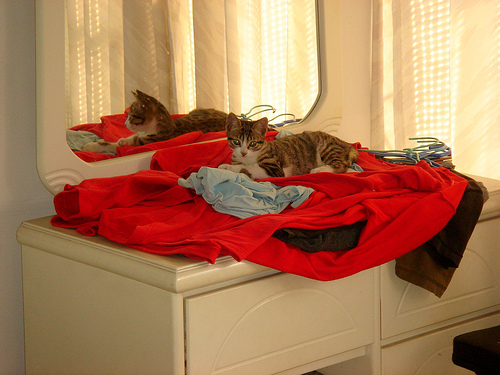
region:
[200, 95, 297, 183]
the head of a cat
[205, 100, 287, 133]
the ears of a cat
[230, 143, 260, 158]
the nose of a cat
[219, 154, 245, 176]
the paw of a cat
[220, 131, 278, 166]
the eyes of a cat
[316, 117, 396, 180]
the tail of a cat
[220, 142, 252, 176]
the mouth of a cat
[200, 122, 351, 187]
the body of a cat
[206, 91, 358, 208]
a cat laying down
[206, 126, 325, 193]
the leg of a cat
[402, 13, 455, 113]
curtains over the window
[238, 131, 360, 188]
cat on the blanket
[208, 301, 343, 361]
drawer of the cabinet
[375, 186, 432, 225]
the blanket is red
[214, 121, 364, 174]
the cat is laying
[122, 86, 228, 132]
reflection of the cat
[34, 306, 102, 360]
side of the cabinet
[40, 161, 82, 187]
corner of the mirror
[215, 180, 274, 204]
the clothing is blue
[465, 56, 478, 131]
the curtains are tan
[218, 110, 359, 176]
A striped cat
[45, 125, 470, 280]
A red piece of clothing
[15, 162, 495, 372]
An off white dresser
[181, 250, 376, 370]
A dresser drawer front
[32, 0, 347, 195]
A framed mirror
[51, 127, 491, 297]
A stack of clothes on hangers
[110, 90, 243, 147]
The reflection of a cat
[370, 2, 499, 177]
A light colored curtain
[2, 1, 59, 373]
A grey painted wall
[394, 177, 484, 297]
A sleeve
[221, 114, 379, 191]
cat laying on the counter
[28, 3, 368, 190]
mirror on the wall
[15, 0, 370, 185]
thick white frame around the wall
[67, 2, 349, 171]
reflection in the mirror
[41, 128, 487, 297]
bright orange fabric on the counter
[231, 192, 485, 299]
fabric hanging over the edge of the counter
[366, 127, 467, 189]
a stack of hangers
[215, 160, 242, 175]
the paw is white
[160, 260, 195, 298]
corner of the counter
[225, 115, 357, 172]
a kitten laying on a red blanket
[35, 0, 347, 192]
a white frame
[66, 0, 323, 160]
a mirror in a white frame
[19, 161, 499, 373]
a white dresser against a wall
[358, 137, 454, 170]
colorful hangers on a dresser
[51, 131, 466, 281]
a re blanket on a dresser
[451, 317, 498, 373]
edge of a black stool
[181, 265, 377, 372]
a white drawer on a dresser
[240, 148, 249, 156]
pink nose of a cat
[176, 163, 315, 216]
a blue cloth on top of a red blanket